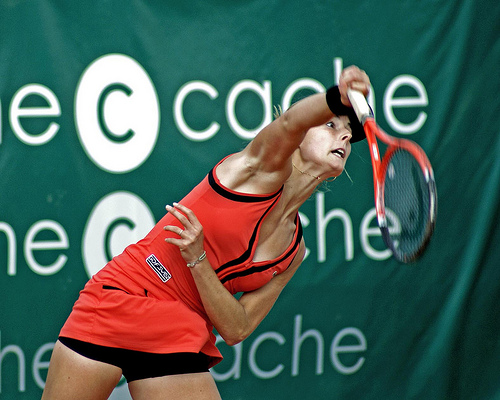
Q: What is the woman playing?
A: Tennis.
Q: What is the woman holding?
A: A tennis racket.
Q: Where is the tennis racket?
A: In the woman's hand.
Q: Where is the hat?
A: On the woman's head.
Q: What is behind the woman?
A: A sign.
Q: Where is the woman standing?
A: A tennis court.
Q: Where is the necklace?
A: Around the woman's neck.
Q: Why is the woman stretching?
A: To hit the ball.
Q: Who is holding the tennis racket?
A: The woman.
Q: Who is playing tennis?
A: Woman in red dress.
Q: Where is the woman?
A: Tennis court.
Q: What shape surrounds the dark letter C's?
A: White.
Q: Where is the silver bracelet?
A: Left wrist.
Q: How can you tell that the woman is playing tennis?
A: Holding a tennis racket.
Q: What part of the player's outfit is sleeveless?
A: Shirt.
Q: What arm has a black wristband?
A: Right.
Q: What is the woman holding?
A: A tennis racket.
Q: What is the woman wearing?
A: A shirt.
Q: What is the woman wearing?
A: Shorts.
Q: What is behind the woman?
A: A banner.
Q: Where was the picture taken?
A: A tennis court.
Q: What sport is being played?
A: Tennis.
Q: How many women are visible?
A: One.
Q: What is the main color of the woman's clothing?
A: Red.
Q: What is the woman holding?
A: A tennis racquet.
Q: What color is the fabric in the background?
A: Green.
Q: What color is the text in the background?
A: White.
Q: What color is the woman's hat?
A: Black.